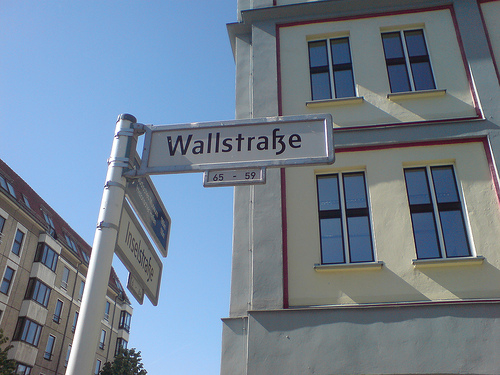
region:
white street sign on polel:
[130, 118, 336, 168]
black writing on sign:
[153, 126, 307, 156]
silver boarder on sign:
[143, 158, 328, 170]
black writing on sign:
[200, 168, 266, 185]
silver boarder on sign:
[197, 182, 257, 187]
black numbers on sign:
[215, 169, 257, 184]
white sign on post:
[115, 216, 172, 284]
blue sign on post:
[130, 185, 165, 248]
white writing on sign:
[121, 184, 160, 219]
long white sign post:
[29, 111, 130, 373]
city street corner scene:
[1, 32, 493, 374]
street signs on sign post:
[106, 110, 343, 310]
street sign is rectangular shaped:
[132, 112, 344, 176]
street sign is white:
[138, 105, 344, 178]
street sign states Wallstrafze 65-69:
[151, 117, 341, 191]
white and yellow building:
[209, 69, 499, 374]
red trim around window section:
[274, 136, 499, 318]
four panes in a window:
[308, 157, 399, 279]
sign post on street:
[56, 115, 140, 366]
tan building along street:
[3, 157, 140, 374]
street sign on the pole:
[122, 113, 347, 190]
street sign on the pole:
[106, 137, 186, 312]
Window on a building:
[396, 155, 486, 271]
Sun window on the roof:
[18, 192, 34, 209]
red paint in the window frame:
[273, 20, 483, 120]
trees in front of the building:
[91, 339, 140, 372]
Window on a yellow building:
[293, 30, 370, 114]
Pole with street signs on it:
[103, 105, 344, 294]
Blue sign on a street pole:
[126, 151, 183, 261]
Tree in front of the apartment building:
[98, 333, 146, 373]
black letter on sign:
[161, 132, 193, 155]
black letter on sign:
[188, 135, 203, 155]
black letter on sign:
[202, 129, 214, 154]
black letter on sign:
[211, 129, 222, 155]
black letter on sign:
[221, 135, 232, 155]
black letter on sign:
[231, 130, 246, 154]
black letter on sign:
[243, 134, 255, 154]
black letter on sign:
[256, 135, 266, 149]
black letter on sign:
[269, 125, 287, 155]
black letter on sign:
[286, 132, 304, 153]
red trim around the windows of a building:
[260, 7, 499, 309]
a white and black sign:
[127, 108, 342, 179]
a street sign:
[44, 103, 340, 373]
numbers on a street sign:
[202, 167, 264, 186]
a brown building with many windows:
[0, 153, 135, 374]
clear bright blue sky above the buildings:
[2, 1, 257, 371]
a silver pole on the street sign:
[66, 115, 143, 371]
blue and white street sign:
[128, 166, 180, 248]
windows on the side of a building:
[297, 5, 486, 293]